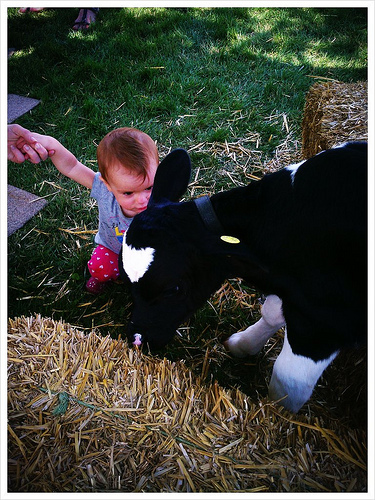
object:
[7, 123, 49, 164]
hand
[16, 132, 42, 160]
hand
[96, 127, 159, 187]
hair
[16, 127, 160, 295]
baby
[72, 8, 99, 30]
feet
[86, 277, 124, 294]
shoes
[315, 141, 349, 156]
spots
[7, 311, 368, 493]
dry grass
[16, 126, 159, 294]
pant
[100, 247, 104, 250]
heart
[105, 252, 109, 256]
heart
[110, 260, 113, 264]
heart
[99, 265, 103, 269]
heart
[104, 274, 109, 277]
heart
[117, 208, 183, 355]
face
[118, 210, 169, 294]
forehead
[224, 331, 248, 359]
hoof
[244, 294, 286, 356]
calf's leg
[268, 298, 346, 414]
front leg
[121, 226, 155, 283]
patch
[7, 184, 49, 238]
carpet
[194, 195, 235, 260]
collar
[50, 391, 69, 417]
piece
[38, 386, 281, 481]
rope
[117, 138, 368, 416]
calf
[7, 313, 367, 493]
hay bale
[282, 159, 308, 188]
spot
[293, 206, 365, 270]
back